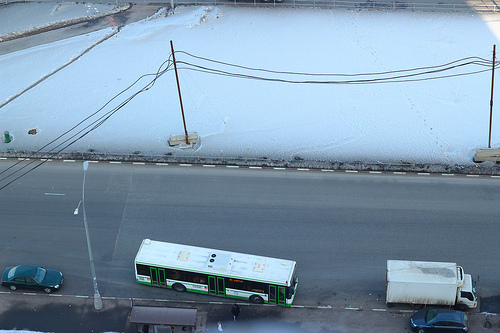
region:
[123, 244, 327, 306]
a bus pulled over to the side of street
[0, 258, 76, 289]
a green car parked on side of road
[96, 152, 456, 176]
white lines painted on a road way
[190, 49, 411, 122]
snow covering the ground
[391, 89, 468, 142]
tracks in the snow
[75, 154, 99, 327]
a tall street light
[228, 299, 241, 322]
a person wearing a black jacket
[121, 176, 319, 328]
The bus is white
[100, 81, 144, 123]
This is a wire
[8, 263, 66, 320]
This is a car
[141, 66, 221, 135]
This is a pole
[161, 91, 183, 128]
The pole is made of metal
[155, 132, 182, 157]
This is a block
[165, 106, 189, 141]
The block is concrete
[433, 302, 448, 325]
This is a window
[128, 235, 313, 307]
a white bus with green doors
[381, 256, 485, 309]
a white commercial truck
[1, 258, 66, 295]
a green four door sedan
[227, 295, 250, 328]
a person standing near the bus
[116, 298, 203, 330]
a building along the road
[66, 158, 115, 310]
a white street lamp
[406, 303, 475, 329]
a blue car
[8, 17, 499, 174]
snow near a road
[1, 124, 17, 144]
a green fire hydrant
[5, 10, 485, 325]
overhead view of some traffic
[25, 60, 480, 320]
overhead view of vehicles and snow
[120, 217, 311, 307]
bus in the street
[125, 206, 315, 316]
big bus in the street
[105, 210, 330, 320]
long bus in the street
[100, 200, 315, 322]
full size bus in the street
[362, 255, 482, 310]
truck in the street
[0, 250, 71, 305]
car in the street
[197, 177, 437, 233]
patch of roadway in view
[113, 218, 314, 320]
big white bus in road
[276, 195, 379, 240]
The pavement is black.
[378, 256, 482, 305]
The truck is white.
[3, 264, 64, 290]
The car is green.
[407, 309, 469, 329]
The van is blue.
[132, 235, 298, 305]
The top of the bus is white.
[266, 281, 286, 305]
The front doors of the bus are green.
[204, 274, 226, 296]
The middle doors of the bus are green.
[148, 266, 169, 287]
The back doors of the bus are green.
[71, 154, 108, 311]
The light pole is tall.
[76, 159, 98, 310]
The light pole is gray.